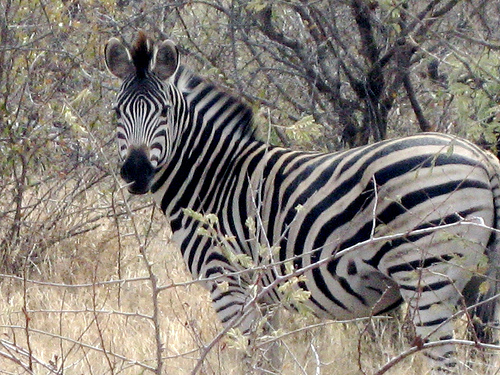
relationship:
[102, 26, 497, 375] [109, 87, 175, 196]
zebra has face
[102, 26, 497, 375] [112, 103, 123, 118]
zebra has eye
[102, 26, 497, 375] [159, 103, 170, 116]
zebra has eye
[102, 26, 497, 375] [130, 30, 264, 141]
zebra has mane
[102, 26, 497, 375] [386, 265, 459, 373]
zebra has leg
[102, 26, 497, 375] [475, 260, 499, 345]
zebra has leg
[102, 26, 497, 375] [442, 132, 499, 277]
zebra has rump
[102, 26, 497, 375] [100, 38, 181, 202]
zebra has head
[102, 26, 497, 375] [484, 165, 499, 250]
zebra has tail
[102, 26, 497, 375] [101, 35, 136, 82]
zebra has ear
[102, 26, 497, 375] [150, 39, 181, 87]
zebra has ear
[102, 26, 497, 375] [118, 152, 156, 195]
zebra has snout